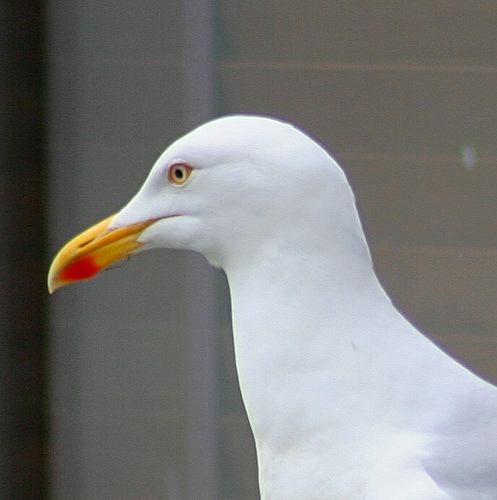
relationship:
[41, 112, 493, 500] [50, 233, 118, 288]
seagull has beak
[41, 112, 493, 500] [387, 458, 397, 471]
seagull has feather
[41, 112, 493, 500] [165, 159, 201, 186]
seagull has eye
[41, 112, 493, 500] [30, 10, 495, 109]
seagull next to structure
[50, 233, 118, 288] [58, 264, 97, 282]
beak has spot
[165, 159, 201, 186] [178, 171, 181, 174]
eye has pupil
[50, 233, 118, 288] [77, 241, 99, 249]
beak has hole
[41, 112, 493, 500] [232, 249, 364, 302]
seagull has neck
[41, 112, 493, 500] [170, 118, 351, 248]
seagull has head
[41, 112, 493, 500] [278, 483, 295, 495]
seagull has feather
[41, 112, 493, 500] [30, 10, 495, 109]
seagull next to window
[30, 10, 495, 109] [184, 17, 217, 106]
window has fram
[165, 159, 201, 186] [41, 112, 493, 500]
eye on seagull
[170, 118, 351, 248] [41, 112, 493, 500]
head of seagull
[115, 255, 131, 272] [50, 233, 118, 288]
string on beak